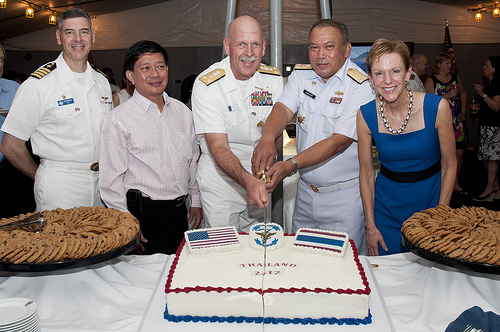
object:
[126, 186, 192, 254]
pants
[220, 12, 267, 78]
head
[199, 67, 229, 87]
patch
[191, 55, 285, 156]
white shirt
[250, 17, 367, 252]
man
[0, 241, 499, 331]
table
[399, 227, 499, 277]
plate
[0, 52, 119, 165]
shirt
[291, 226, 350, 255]
flag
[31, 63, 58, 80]
military patch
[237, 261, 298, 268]
lettering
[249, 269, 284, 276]
writing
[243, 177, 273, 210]
hands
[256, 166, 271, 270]
knife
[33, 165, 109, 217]
pants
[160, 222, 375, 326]
cake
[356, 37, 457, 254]
woman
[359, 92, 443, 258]
dress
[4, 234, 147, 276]
tray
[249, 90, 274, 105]
ribbons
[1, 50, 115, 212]
uniform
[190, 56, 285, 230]
military uniform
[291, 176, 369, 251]
pants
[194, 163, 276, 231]
pants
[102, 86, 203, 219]
shirt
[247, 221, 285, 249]
logo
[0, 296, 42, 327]
plates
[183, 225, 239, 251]
flag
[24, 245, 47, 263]
cookie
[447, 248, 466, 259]
cookie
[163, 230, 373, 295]
border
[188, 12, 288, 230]
man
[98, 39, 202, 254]
man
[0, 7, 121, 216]
man